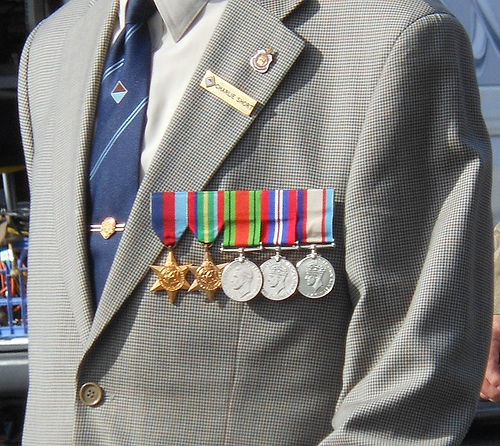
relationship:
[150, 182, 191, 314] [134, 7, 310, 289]
pendant on lapel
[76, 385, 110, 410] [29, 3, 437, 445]
button on jacket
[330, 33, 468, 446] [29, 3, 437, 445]
sleeve on jacket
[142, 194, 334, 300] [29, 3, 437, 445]
medal on jacket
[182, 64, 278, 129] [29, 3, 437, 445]
name tag on jacket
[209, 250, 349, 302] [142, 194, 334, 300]
coins on medal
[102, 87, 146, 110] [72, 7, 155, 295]
diamond on tie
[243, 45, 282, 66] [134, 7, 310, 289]
pin on lapel